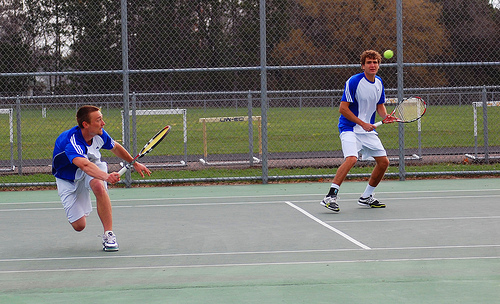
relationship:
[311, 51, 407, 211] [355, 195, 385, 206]
man wearing shoe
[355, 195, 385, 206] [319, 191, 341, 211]
shoe wearing shoe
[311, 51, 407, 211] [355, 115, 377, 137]
man has hand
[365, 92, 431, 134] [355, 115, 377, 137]
racket in hand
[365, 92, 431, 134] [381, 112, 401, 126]
racket in hand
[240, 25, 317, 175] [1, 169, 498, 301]
metal pole near tennis court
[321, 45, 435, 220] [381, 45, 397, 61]
guy is about to hit tennis ball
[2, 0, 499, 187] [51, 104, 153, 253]
fence behind man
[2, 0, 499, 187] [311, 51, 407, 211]
fence behind man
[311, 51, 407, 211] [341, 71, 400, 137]
man wearing shirt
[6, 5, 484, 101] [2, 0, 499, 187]
forest outside a fence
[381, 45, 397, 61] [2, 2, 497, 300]
tennis ball on air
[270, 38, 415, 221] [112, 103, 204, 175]
man with racket